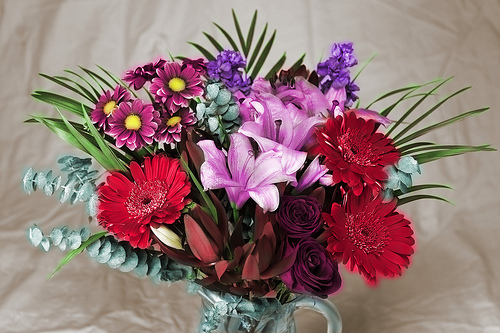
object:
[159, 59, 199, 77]
petals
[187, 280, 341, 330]
glass jug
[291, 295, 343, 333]
handle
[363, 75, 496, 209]
blades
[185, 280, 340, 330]
pitcher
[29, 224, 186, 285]
blue plant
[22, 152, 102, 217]
blue plant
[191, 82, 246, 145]
blue plant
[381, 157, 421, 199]
blue plant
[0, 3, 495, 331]
fabric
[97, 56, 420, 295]
flower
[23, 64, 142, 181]
leaves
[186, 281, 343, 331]
pitcher vase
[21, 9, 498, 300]
arrangement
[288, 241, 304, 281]
petals